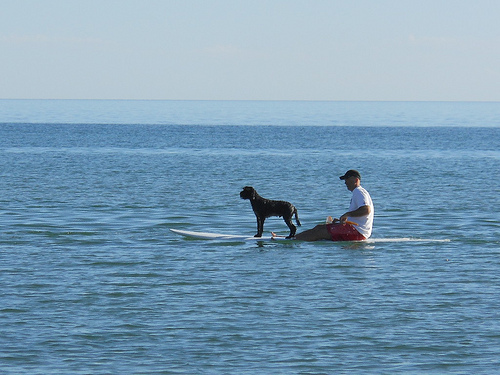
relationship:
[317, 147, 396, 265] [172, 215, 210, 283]
man and dog on a surfboard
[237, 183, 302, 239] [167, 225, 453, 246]
dog standing on surfboard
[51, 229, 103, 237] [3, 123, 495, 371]
ripple in water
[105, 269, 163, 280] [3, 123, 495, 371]
ripple in water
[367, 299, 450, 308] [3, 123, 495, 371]
ripple in water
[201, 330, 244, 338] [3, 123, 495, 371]
ripple in water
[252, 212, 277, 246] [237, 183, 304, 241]
leg on dog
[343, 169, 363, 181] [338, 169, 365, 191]
hat on head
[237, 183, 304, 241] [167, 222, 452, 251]
dog on surfboard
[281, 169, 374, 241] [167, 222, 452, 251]
man on surfboard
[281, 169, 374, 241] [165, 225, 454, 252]
man sitting on surfboard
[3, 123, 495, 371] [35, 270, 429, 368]
water appears calm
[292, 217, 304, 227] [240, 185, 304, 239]
tail of dog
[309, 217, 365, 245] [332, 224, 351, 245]
pair of shorts